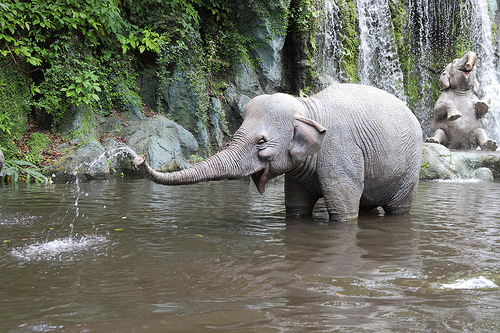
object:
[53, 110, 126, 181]
boulder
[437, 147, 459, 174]
ground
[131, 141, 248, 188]
trunk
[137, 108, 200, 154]
large rocks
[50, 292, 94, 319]
water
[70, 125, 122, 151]
rock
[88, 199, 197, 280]
brown water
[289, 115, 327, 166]
ear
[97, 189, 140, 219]
water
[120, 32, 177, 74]
plants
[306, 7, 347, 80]
waterfall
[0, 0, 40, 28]
leaves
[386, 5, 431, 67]
waterfall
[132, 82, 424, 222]
elephant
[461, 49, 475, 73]
trunk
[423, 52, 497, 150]
elephant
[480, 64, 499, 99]
white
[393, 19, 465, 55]
grass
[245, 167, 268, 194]
mouth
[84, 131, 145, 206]
elephant water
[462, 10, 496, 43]
water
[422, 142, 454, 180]
boulder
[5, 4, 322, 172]
side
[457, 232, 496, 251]
water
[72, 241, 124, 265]
water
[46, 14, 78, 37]
leaves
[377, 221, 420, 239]
water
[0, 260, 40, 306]
water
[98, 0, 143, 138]
cliff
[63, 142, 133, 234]
water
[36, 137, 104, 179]
riverbank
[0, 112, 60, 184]
foilage